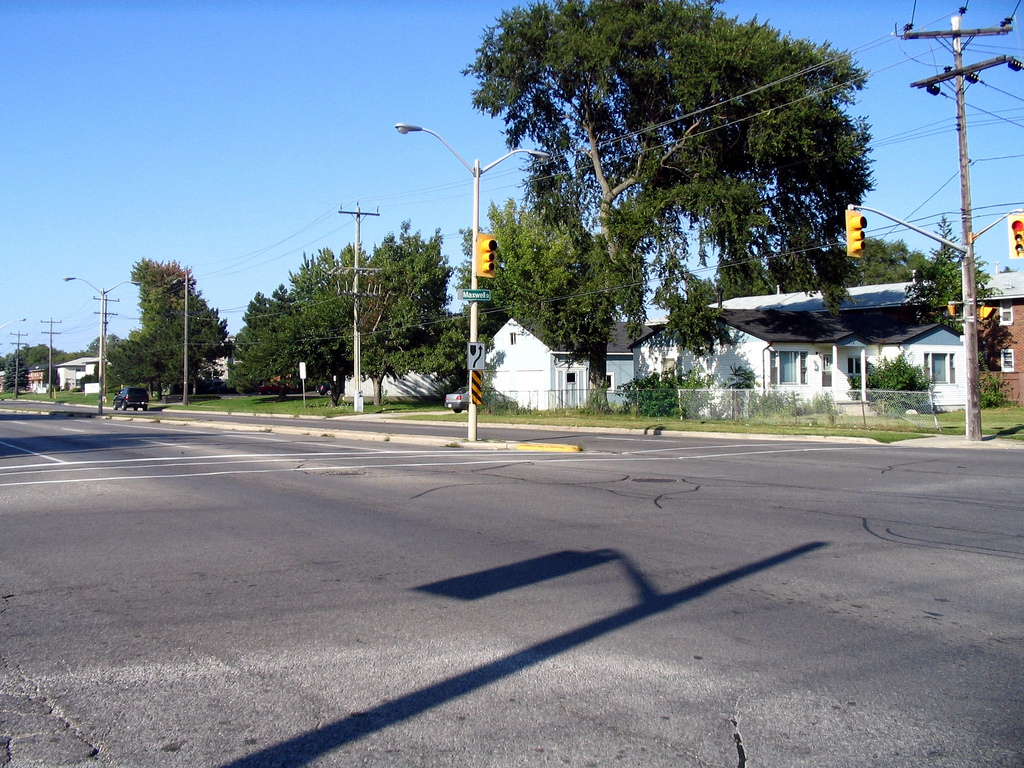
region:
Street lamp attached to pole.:
[388, 123, 483, 431]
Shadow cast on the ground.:
[233, 540, 856, 765]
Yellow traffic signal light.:
[468, 225, 498, 280]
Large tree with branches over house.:
[476, 16, 884, 447]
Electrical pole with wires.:
[890, 9, 1023, 430]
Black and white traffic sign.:
[457, 342, 490, 374]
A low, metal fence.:
[675, 375, 973, 426]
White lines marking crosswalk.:
[0, 446, 526, 500]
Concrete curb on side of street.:
[489, 411, 1022, 460]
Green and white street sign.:
[458, 288, 491, 301]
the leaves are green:
[623, 33, 722, 91]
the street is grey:
[196, 490, 334, 601]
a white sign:
[464, 340, 494, 378]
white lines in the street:
[140, 449, 218, 488]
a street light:
[389, 115, 429, 142]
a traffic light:
[848, 212, 864, 257]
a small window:
[993, 342, 1020, 378]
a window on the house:
[771, 348, 807, 383]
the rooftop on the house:
[769, 304, 815, 339]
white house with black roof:
[490, 271, 946, 445]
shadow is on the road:
[148, 505, 860, 765]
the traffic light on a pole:
[463, 222, 505, 286]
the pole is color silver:
[456, 144, 494, 448]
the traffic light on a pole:
[836, 191, 878, 269]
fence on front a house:
[667, 368, 944, 442]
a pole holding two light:
[376, 107, 554, 449]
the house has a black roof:
[480, 302, 655, 414]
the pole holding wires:
[372, 8, 1020, 192]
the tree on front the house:
[449, 6, 958, 436]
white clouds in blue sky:
[22, 48, 71, 99]